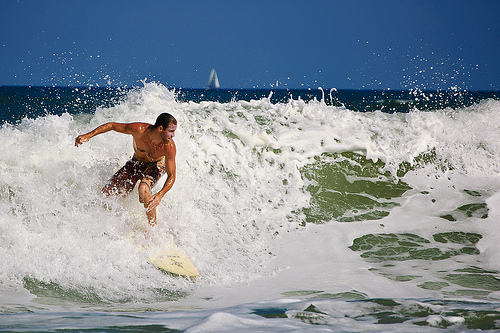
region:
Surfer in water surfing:
[70, 105, 202, 284]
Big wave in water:
[3, 80, 498, 275]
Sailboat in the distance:
[192, 59, 233, 102]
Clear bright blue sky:
[0, 0, 497, 92]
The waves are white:
[211, 85, 498, 276]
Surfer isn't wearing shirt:
[70, 108, 183, 208]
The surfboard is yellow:
[116, 212, 207, 287]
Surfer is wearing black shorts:
[73, 108, 184, 233]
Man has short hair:
[140, 107, 190, 147]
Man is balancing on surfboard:
[70, 106, 208, 286]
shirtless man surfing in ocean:
[61, 99, 202, 241]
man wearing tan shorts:
[113, 150, 163, 195]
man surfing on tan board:
[98, 202, 193, 287]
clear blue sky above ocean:
[14, 12, 181, 70]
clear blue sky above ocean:
[161, 15, 393, 57]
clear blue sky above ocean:
[367, 15, 477, 73]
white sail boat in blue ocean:
[201, 58, 226, 89]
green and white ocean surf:
[303, 125, 425, 247]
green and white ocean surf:
[16, 160, 95, 300]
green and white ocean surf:
[209, 132, 345, 244]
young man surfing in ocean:
[57, 105, 199, 232]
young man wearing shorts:
[114, 147, 166, 193]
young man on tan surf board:
[92, 210, 203, 285]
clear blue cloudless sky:
[8, 10, 205, 64]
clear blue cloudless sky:
[178, 14, 374, 61]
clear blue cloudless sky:
[338, 8, 481, 54]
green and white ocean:
[285, 107, 422, 215]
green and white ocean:
[246, 203, 484, 285]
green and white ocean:
[26, 137, 83, 304]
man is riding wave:
[71, 115, 280, 275]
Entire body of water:
[1, 87, 498, 332]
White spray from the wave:
[0, 40, 499, 295]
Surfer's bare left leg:
[138, 173, 154, 224]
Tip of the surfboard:
[145, 247, 195, 272]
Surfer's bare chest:
[131, 139, 166, 159]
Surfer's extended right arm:
[73, 120, 134, 147]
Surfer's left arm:
[148, 153, 176, 207]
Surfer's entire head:
[154, 112, 176, 140]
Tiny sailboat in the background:
[206, 58, 221, 86]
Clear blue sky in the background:
[0, 0, 497, 88]